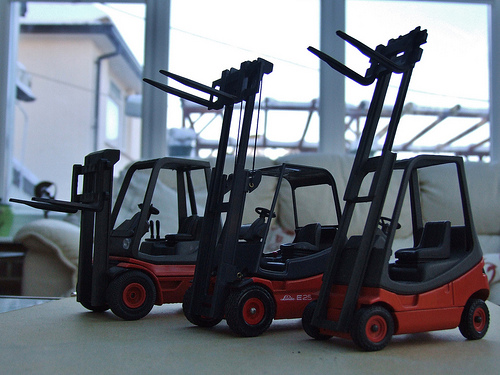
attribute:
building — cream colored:
[19, 8, 159, 233]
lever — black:
[195, 32, 260, 190]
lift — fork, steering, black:
[163, 124, 359, 361]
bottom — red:
[269, 278, 323, 328]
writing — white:
[271, 289, 328, 320]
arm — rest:
[127, 37, 289, 127]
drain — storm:
[12, 282, 47, 327]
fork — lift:
[158, 57, 353, 365]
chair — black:
[278, 222, 327, 277]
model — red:
[109, 112, 271, 351]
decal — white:
[247, 275, 323, 331]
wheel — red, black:
[244, 280, 279, 319]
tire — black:
[99, 255, 153, 309]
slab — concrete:
[47, 214, 75, 227]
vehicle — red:
[195, 102, 345, 372]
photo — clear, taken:
[48, 50, 456, 338]